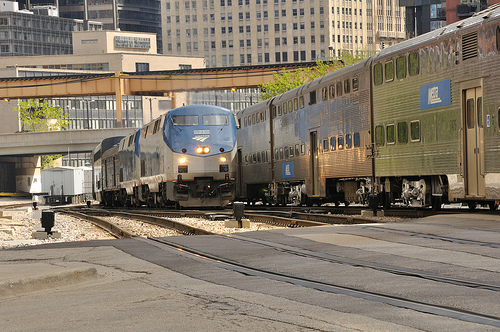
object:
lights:
[178, 154, 188, 166]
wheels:
[261, 177, 290, 205]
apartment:
[161, 0, 403, 64]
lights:
[216, 153, 232, 163]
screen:
[350, 132, 362, 149]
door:
[461, 76, 483, 198]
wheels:
[389, 176, 442, 211]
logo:
[423, 86, 441, 106]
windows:
[202, 115, 229, 127]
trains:
[238, 4, 500, 205]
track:
[249, 204, 500, 250]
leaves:
[27, 104, 49, 120]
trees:
[17, 104, 69, 131]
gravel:
[68, 220, 91, 238]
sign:
[417, 81, 452, 108]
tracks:
[1, 61, 354, 101]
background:
[3, 2, 497, 53]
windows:
[406, 120, 423, 142]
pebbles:
[66, 220, 100, 239]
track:
[60, 208, 212, 243]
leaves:
[275, 74, 291, 85]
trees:
[267, 58, 366, 99]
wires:
[1, 73, 116, 88]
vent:
[458, 31, 480, 62]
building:
[20, 67, 122, 207]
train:
[89, 103, 239, 207]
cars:
[271, 54, 373, 198]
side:
[240, 6, 500, 199]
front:
[164, 103, 238, 201]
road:
[1, 214, 500, 329]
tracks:
[148, 232, 497, 328]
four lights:
[171, 148, 232, 165]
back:
[40, 165, 76, 195]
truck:
[43, 166, 93, 196]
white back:
[14, 170, 43, 194]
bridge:
[0, 125, 141, 154]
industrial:
[1, 28, 207, 113]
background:
[0, 66, 342, 127]